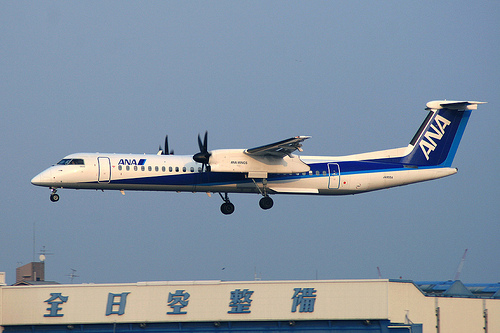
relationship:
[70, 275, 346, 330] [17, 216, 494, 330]
letters on building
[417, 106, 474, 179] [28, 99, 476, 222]
logo on plane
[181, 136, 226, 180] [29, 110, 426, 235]
propeller on plane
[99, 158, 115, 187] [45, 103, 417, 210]
door on plane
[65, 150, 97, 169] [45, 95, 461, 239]
window on airplane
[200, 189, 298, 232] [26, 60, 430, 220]
landing gear on airplane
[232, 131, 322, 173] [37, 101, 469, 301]
wing on airplane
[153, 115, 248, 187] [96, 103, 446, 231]
propellers on plane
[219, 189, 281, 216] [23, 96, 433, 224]
landing gear on plane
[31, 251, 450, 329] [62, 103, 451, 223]
building below plane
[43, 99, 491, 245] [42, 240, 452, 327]
plane above building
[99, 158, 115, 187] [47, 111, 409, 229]
door on plane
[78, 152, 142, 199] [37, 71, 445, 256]
door on airplane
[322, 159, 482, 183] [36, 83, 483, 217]
door on airplane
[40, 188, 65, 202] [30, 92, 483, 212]
tire on airplane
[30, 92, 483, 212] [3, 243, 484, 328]
airplane flying building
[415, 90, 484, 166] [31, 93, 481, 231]
tail of airplane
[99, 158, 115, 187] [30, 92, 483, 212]
door of airplane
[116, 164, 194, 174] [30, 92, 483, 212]
windows of airplane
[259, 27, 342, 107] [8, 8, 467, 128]
clouds in sky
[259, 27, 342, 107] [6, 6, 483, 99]
clouds in sky